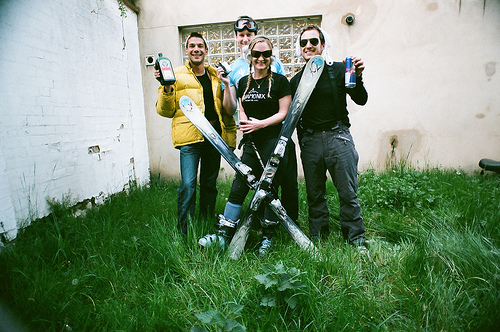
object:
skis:
[178, 95, 327, 263]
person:
[289, 22, 375, 254]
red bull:
[342, 54, 359, 89]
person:
[195, 31, 300, 257]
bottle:
[213, 58, 233, 77]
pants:
[299, 123, 368, 246]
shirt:
[286, 58, 369, 132]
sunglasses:
[298, 38, 324, 47]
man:
[152, 29, 238, 237]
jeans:
[174, 141, 224, 240]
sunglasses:
[249, 49, 273, 60]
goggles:
[231, 19, 260, 35]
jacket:
[154, 59, 238, 151]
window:
[176, 13, 326, 80]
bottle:
[152, 51, 176, 86]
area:
[3, 165, 497, 330]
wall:
[1, 1, 152, 239]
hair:
[241, 35, 274, 99]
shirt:
[220, 53, 284, 91]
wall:
[137, 1, 499, 182]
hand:
[153, 69, 174, 89]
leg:
[174, 145, 200, 235]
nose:
[194, 48, 200, 53]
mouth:
[191, 53, 204, 57]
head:
[181, 29, 210, 67]